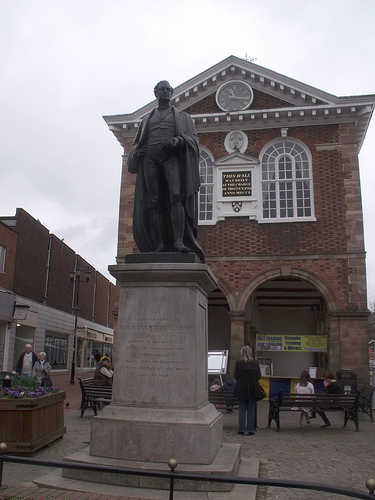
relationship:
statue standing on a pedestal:
[123, 79, 205, 262] [1, 250, 265, 498]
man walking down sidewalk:
[4, 338, 55, 388] [55, 370, 83, 406]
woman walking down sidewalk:
[31, 347, 61, 391] [55, 370, 83, 406]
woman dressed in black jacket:
[221, 331, 261, 440] [231, 355, 267, 405]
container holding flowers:
[1, 398, 79, 455] [3, 372, 60, 403]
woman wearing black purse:
[235, 343, 266, 440] [245, 380, 275, 410]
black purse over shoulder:
[245, 380, 275, 410] [247, 357, 259, 370]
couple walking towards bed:
[17, 340, 57, 393] [7, 382, 77, 452]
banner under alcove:
[254, 332, 327, 351] [207, 275, 325, 401]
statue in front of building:
[123, 79, 205, 262] [82, 47, 369, 409]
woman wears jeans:
[235, 343, 266, 440] [239, 387, 257, 434]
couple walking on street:
[17, 340, 57, 393] [51, 366, 99, 407]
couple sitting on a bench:
[279, 359, 350, 428] [269, 394, 359, 436]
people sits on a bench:
[97, 357, 110, 379] [223, 361, 374, 433]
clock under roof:
[205, 75, 259, 119] [126, 50, 348, 121]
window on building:
[255, 146, 327, 231] [131, 75, 327, 343]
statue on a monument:
[123, 79, 205, 262] [59, 264, 257, 491]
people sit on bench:
[95, 353, 114, 380] [79, 375, 114, 417]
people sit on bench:
[208, 371, 235, 390] [206, 388, 239, 410]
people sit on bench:
[292, 368, 339, 394] [263, 387, 362, 430]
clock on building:
[214, 75, 256, 119] [82, 47, 369, 409]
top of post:
[164, 456, 179, 471] [167, 468, 178, 499]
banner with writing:
[254, 332, 327, 351] [257, 335, 301, 350]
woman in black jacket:
[235, 343, 266, 440] [232, 360, 266, 404]